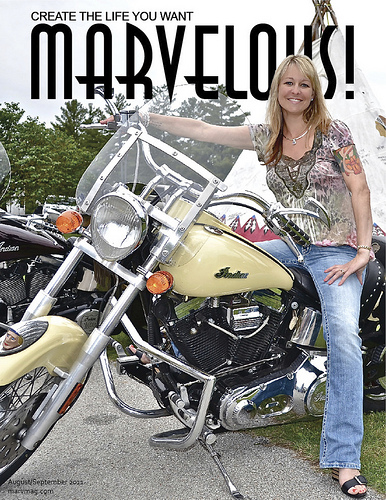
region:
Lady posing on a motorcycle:
[84, 48, 380, 497]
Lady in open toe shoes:
[317, 448, 372, 498]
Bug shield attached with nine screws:
[68, 78, 271, 273]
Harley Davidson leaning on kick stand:
[0, 99, 385, 498]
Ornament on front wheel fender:
[0, 317, 50, 357]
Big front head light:
[85, 185, 148, 264]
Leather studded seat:
[285, 247, 384, 314]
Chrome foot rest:
[97, 290, 219, 458]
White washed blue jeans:
[251, 225, 372, 473]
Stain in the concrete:
[81, 407, 123, 430]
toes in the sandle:
[347, 482, 375, 498]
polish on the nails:
[346, 483, 373, 493]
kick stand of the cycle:
[208, 439, 258, 496]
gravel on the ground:
[16, 435, 320, 498]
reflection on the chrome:
[234, 360, 321, 414]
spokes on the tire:
[3, 365, 61, 427]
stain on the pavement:
[67, 405, 124, 431]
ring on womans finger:
[332, 264, 343, 272]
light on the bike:
[134, 269, 178, 301]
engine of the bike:
[158, 299, 293, 400]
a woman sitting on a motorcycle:
[45, 61, 349, 498]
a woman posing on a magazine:
[23, 40, 377, 498]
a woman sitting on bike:
[38, 42, 383, 463]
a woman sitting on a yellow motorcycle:
[37, 44, 378, 478]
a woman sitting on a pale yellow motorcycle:
[18, 32, 385, 486]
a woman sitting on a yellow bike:
[44, 53, 346, 491]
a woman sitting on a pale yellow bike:
[45, 22, 379, 497]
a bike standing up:
[16, 97, 385, 480]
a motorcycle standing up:
[63, 66, 383, 400]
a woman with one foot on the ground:
[45, 28, 384, 427]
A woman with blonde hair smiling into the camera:
[269, 53, 323, 115]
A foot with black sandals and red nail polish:
[335, 462, 373, 498]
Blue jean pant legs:
[318, 369, 364, 469]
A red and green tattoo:
[332, 144, 365, 182]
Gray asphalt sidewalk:
[90, 427, 155, 493]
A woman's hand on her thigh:
[322, 240, 379, 293]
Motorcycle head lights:
[47, 176, 194, 310]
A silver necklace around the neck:
[276, 127, 317, 146]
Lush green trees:
[34, 140, 79, 169]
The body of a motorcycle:
[93, 187, 309, 435]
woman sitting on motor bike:
[5, 55, 373, 492]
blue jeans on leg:
[255, 236, 379, 471]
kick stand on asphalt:
[199, 438, 246, 498]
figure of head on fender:
[0, 319, 85, 385]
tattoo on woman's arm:
[336, 144, 361, 177]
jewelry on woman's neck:
[281, 120, 314, 147]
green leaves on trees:
[5, 85, 248, 207]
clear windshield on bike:
[76, 84, 255, 269]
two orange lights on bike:
[57, 210, 170, 296]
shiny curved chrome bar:
[101, 354, 169, 416]